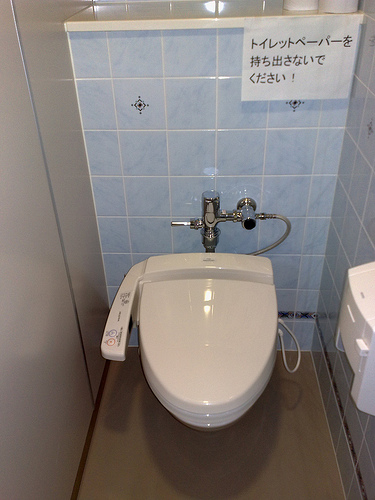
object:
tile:
[216, 132, 265, 176]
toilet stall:
[0, 0, 375, 500]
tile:
[217, 76, 267, 129]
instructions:
[242, 19, 359, 101]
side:
[0, 0, 109, 500]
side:
[310, 80, 375, 499]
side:
[128, 218, 170, 255]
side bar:
[100, 256, 144, 362]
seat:
[138, 280, 282, 431]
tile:
[162, 29, 215, 78]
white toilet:
[102, 253, 278, 427]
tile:
[85, 130, 123, 176]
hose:
[278, 315, 301, 373]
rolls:
[320, 1, 357, 13]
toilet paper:
[282, 1, 316, 13]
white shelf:
[63, 0, 368, 32]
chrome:
[171, 189, 291, 256]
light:
[204, 290, 211, 302]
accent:
[286, 100, 305, 112]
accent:
[131, 96, 149, 115]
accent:
[278, 311, 317, 320]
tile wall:
[67, 25, 361, 351]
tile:
[261, 175, 310, 217]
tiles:
[68, 27, 375, 423]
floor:
[72, 349, 347, 500]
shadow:
[106, 345, 300, 500]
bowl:
[138, 254, 278, 432]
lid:
[142, 281, 278, 415]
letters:
[250, 35, 353, 84]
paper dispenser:
[335, 260, 375, 414]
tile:
[113, 79, 165, 129]